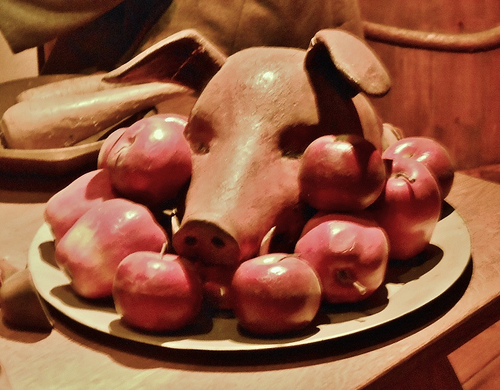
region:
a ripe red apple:
[107, 113, 195, 200]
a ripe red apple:
[44, 159, 112, 244]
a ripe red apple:
[53, 192, 165, 297]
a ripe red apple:
[112, 250, 202, 332]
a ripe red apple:
[228, 250, 320, 330]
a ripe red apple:
[294, 211, 388, 297]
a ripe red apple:
[298, 134, 383, 211]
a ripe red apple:
[360, 150, 439, 261]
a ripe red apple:
[381, 134, 455, 207]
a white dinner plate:
[28, 196, 473, 351]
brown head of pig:
[145, 20, 347, 238]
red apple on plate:
[116, 250, 185, 327]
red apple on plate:
[61, 201, 148, 256]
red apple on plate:
[241, 258, 308, 321]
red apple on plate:
[305, 225, 390, 275]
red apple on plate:
[311, 137, 365, 206]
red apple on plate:
[393, 174, 431, 239]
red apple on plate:
[418, 148, 467, 188]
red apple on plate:
[53, 176, 95, 223]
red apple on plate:
[126, 113, 193, 199]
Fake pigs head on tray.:
[107, 28, 410, 278]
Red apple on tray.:
[235, 252, 322, 337]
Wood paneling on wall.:
[411, 50, 498, 137]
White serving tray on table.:
[25, 163, 470, 350]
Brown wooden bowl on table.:
[1, 73, 137, 168]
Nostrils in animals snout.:
[174, 215, 241, 265]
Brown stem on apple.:
[390, 160, 420, 190]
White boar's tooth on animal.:
[252, 220, 277, 255]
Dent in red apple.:
[319, 220, 369, 270]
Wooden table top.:
[453, 162, 498, 339]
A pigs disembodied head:
[103, 28, 390, 260]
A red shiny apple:
[110, 242, 202, 330]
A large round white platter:
[27, 157, 472, 350]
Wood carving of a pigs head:
[102, 25, 382, 259]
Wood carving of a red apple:
[110, 243, 203, 332]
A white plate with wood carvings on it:
[27, 27, 472, 349]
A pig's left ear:
[304, 25, 387, 93]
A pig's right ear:
[102, 27, 222, 91]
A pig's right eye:
[184, 120, 214, 153]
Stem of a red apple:
[342, 270, 367, 295]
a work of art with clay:
[3, 6, 498, 387]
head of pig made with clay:
[95, 22, 401, 267]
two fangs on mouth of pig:
[155, 200, 280, 265]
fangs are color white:
[157, 206, 274, 261]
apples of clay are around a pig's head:
[28, 21, 461, 346]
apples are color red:
[40, 110, 467, 345]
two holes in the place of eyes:
[175, 102, 332, 165]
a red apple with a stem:
[293, 210, 396, 311]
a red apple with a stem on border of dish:
[104, 235, 211, 342]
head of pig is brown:
[97, 23, 403, 275]